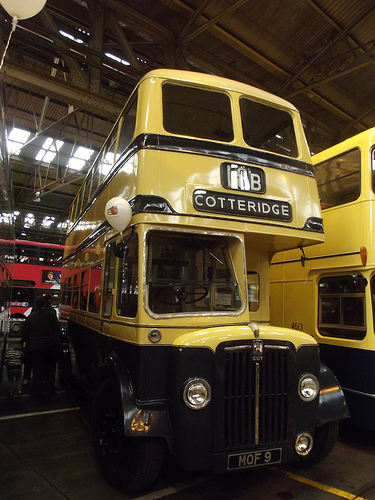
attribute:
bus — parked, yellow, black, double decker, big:
[54, 64, 353, 494]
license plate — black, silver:
[226, 446, 285, 473]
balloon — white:
[104, 193, 133, 240]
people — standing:
[18, 290, 67, 401]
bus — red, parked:
[2, 235, 106, 341]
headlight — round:
[296, 370, 321, 403]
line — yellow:
[274, 465, 366, 499]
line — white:
[2, 402, 86, 423]